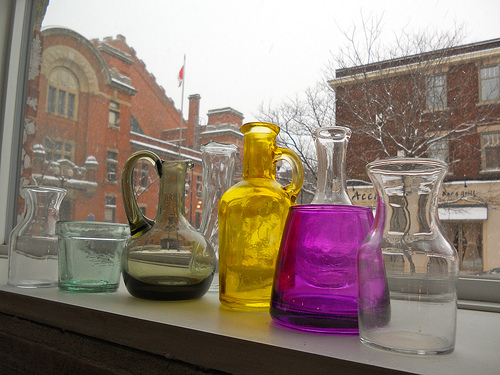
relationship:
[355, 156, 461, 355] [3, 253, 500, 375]
vase on shelving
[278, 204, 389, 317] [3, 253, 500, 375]
vase on shelving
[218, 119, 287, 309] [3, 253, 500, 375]
vase on shelving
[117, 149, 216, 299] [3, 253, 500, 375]
vase on shelving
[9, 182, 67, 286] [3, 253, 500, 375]
vase on shelving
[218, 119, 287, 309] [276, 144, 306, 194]
vase has handle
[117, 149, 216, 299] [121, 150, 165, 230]
vase has handle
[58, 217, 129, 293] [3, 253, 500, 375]
vase on shelving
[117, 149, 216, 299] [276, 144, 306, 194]
vase has handle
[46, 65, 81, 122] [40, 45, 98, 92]
window has arch